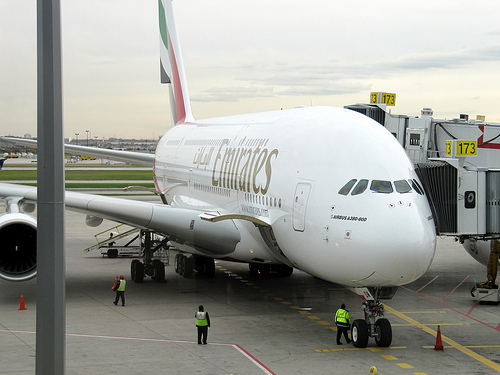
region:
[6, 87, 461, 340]
An Emirati airplane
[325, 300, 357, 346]
An airport work standing by a plane's wheels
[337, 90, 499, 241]
Boarding tunnels against the plane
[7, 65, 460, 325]
A plane being boarded for take-off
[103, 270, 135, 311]
An airport worker carrying an orange traffic cone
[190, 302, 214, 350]
An airport worker standing on a red line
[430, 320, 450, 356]
An orange traffic cone in front of the plane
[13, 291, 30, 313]
An orange traffic cone in front of a jet engine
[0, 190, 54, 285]
A jet engine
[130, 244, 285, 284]
The plane's wheels and landing gear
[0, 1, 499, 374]
an Emirates airliner is parked at the tarmac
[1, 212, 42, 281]
a jet engine mounted on the wing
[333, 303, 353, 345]
an airport worker wearing a fluorescent yellow safety vest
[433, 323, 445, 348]
an orange traffic cone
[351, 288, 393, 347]
the front landing gear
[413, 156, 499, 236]
a portable passenger boarding bridge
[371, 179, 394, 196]
the front windshield of the cockpit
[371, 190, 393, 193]
the front windshield wiper blade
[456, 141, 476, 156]
the identification number of the terminal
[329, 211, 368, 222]
the identification number of the jet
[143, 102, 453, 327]
plane parked on tarmac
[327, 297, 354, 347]
airport worker in neon coat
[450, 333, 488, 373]
yellow lines on tarmac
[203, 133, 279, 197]
name of airline on plane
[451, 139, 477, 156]
black numbers on yellow sign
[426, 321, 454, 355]
orange pylon on tarmac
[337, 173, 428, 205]
windows on plane cockpit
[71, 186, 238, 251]
wing on side of plane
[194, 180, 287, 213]
windows for plane passengers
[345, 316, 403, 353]
tires on landing gear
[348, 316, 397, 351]
two front airplane wheels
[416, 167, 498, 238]
passenger airplane loading ramp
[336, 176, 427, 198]
six front airplane windows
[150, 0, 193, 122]
white, purple, green and red airplane tail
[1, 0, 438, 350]
white airplane on concrete tarmac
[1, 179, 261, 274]
white and grey airplane wing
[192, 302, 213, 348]
airport worker in green vest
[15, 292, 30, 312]
orange traffic cone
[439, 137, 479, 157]
yellow and black numbered signs on airplane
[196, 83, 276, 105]
grey clouds in blue sky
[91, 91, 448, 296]
airplane parked on tarmac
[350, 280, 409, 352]
landing gear under nose of plane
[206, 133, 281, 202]
name of airline on side of plane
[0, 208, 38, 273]
jet engine under wing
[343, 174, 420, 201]
cockpit windows on front of plane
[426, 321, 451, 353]
orange pylons on tarmac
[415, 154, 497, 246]
walkway for boarding passengers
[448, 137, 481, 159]
black numbers on yellow background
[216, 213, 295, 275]
open door under plane